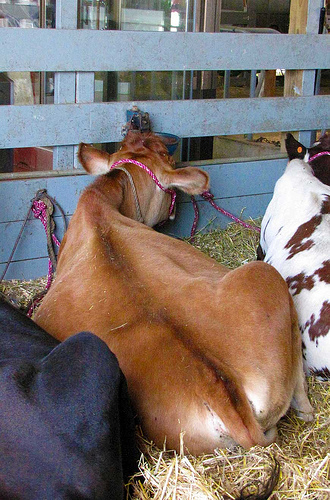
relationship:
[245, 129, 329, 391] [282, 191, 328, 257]
cow has spot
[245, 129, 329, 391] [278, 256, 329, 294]
cow has spot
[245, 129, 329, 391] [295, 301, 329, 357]
cow has spot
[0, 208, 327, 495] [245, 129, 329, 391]
straw under cow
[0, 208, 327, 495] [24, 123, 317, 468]
straw under cow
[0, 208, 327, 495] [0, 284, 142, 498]
straw under cow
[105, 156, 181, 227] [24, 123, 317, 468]
rope on a cow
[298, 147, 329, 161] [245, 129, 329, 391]
rope on a cow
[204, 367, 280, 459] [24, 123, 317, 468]
tail of a cow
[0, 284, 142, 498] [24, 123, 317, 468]
cow next to cow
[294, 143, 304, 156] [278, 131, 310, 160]
tag on an ear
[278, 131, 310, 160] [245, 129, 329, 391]
ear of a cow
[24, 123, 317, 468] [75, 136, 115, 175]
cow has left ear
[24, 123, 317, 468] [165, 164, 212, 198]
cow has right ear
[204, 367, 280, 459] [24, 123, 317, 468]
tail of cow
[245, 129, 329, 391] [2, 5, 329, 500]
cow in a pen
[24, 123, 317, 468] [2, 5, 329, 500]
cow in a pen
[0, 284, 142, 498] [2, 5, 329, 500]
cow in a pen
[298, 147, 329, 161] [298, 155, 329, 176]
rope tied around a neck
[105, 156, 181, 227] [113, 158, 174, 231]
rope tied around a neck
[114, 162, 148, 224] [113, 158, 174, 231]
rope tied around a neck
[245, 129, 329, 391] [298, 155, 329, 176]
cow has a neck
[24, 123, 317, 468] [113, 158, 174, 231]
cow has a neck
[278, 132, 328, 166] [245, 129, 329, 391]
head of a cow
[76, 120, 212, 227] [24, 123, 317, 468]
head of a cow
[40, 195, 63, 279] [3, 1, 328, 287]
rope tied to a fence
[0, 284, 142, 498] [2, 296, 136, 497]
cow has fur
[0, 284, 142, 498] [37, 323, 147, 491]
cow has hind quarter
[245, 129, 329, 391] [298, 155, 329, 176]
cow has neck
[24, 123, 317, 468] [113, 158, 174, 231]
cow has neck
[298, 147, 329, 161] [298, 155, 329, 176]
rope around neck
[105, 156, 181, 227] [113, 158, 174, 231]
rope around neck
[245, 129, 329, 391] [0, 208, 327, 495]
cow laying in straw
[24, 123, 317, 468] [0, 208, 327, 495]
cow laying in straw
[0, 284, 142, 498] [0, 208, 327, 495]
cow laying in straw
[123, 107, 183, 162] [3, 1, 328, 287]
bowl on fence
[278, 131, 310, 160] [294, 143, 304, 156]
ear has tag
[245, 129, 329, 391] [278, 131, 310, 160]
cow has an ear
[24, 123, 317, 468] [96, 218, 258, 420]
cow has stripe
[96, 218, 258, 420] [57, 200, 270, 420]
stripe on back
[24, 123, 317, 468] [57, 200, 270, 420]
cow has back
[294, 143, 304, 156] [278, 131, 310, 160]
tag in an ear